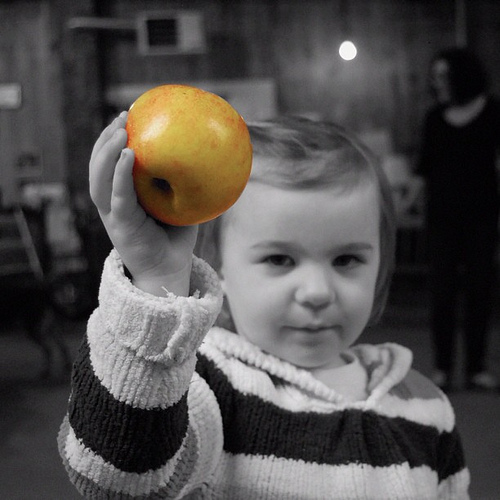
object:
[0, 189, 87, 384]
chair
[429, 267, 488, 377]
pants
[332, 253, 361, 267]
eye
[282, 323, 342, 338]
mouth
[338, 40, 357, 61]
light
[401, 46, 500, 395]
woman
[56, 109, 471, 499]
child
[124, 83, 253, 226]
apple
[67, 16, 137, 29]
wooden shelf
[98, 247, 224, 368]
cuff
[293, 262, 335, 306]
nose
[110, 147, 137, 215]
finger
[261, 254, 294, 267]
eye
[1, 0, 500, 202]
wall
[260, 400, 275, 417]
knitting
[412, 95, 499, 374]
clothes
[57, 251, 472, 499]
sweater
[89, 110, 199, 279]
hand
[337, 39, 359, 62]
fixture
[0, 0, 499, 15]
ceiling